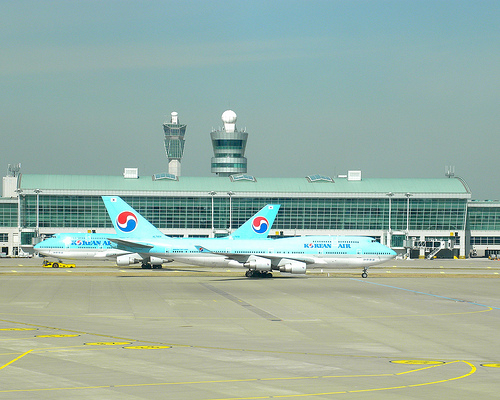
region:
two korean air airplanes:
[32, 189, 397, 281]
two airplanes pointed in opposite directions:
[29, 192, 404, 289]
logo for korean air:
[113, 209, 141, 234]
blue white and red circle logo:
[112, 207, 142, 235]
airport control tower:
[158, 105, 190, 182]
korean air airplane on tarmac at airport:
[100, 193, 398, 293]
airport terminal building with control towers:
[13, 108, 475, 263]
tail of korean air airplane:
[99, 192, 174, 259]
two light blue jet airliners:
[30, 192, 400, 289]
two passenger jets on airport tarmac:
[31, 190, 398, 288]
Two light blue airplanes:
[29, 191, 405, 282]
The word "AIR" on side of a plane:
[335, 240, 354, 253]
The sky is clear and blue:
[1, 2, 498, 202]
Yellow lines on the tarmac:
[1, 318, 498, 398]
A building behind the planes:
[1, 107, 498, 261]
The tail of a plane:
[99, 190, 166, 232]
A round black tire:
[48, 257, 61, 275]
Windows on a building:
[408, 199, 465, 232]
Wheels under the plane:
[138, 261, 167, 274]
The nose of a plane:
[369, 231, 400, 272]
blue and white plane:
[105, 198, 395, 278]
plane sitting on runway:
[36, 201, 280, 268]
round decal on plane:
[118, 211, 138, 232]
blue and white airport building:
[3, 171, 499, 255]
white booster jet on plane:
[281, 260, 306, 276]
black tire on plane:
[362, 270, 368, 277]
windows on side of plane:
[276, 249, 305, 255]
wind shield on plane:
[371, 238, 378, 243]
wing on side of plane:
[206, 250, 315, 267]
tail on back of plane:
[101, 194, 166, 255]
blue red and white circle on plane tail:
[110, 203, 145, 233]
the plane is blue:
[126, 209, 406, 281]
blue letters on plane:
[299, 238, 361, 257]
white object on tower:
[216, 106, 241, 136]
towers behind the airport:
[163, 100, 251, 180]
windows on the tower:
[206, 132, 248, 173]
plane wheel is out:
[358, 260, 375, 282]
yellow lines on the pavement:
[2, 300, 497, 399]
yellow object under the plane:
[38, 259, 78, 276]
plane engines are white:
[244, 251, 313, 282]